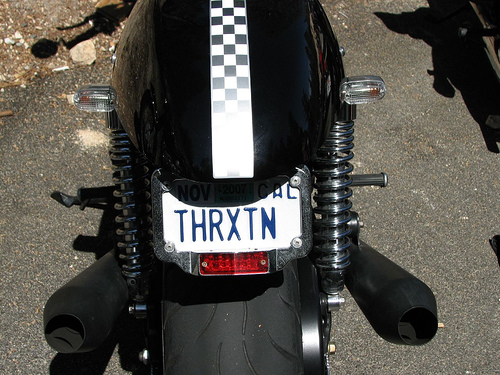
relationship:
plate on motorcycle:
[164, 192, 301, 252] [37, 0, 431, 373]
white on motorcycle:
[212, 116, 254, 176] [37, 0, 431, 373]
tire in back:
[172, 286, 299, 375] [111, 10, 324, 276]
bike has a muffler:
[37, 0, 431, 373] [349, 231, 441, 347]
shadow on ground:
[375, 2, 497, 164] [2, 1, 497, 370]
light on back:
[200, 250, 269, 275] [111, 10, 324, 276]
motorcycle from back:
[37, 0, 431, 373] [111, 10, 324, 276]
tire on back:
[172, 286, 299, 375] [111, 10, 324, 276]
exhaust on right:
[349, 231, 441, 347] [235, 2, 498, 366]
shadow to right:
[375, 2, 497, 164] [235, 2, 498, 366]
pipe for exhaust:
[349, 231, 441, 347] [349, 231, 441, 347]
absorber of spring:
[316, 119, 359, 274] [316, 119, 359, 274]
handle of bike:
[53, 5, 131, 62] [37, 0, 431, 373]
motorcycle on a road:
[37, 0, 431, 373] [2, 1, 497, 370]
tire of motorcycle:
[172, 286, 299, 375] [37, 0, 431, 373]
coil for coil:
[110, 133, 147, 268] [106, 133, 147, 278]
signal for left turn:
[75, 82, 114, 112] [4, 4, 206, 367]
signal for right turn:
[345, 76, 391, 105] [235, 2, 498, 366]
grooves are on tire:
[172, 286, 299, 375] [142, 249, 321, 366]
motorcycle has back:
[37, 0, 431, 373] [37, 0, 431, 373]